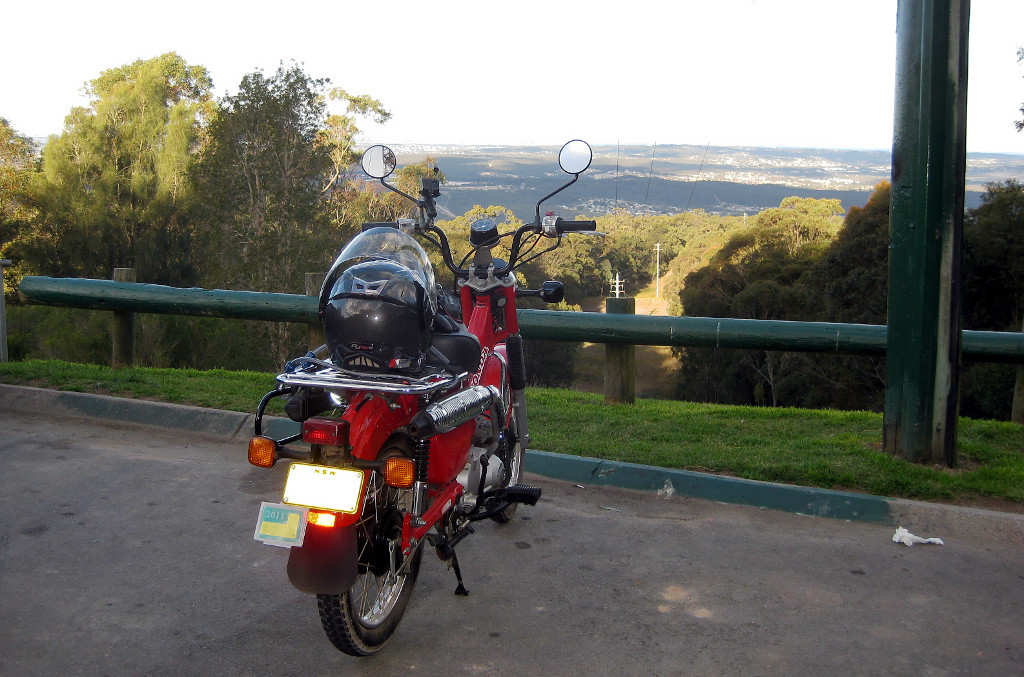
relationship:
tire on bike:
[320, 517, 428, 648] [243, 123, 602, 670]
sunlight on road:
[651, 569, 715, 624] [10, 406, 1019, 673]